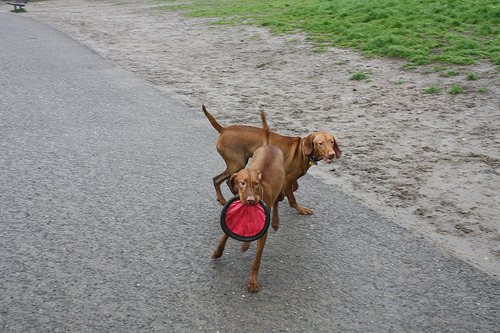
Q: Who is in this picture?
A: Two dogs.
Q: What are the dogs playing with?
A: Frisbee.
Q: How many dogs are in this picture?
A: 2.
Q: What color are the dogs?
A: Brown.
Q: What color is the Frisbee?
A: Red.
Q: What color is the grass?
A: Green.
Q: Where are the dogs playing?
A: On the road.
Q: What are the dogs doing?
A: Playing with a Frisbee.